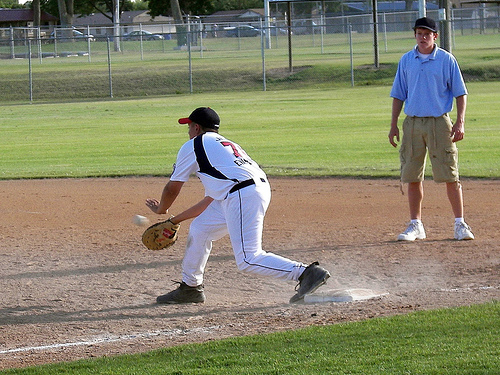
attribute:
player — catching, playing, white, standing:
[173, 96, 320, 295]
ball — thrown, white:
[134, 208, 165, 235]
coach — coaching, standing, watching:
[388, 16, 482, 249]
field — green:
[64, 112, 124, 162]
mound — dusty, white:
[320, 249, 379, 309]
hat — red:
[406, 14, 438, 32]